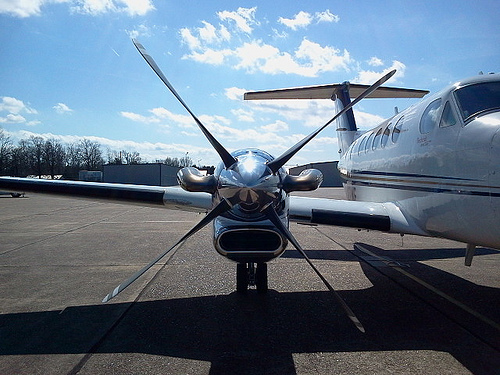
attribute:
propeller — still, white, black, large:
[101, 36, 397, 336]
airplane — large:
[14, 40, 495, 322]